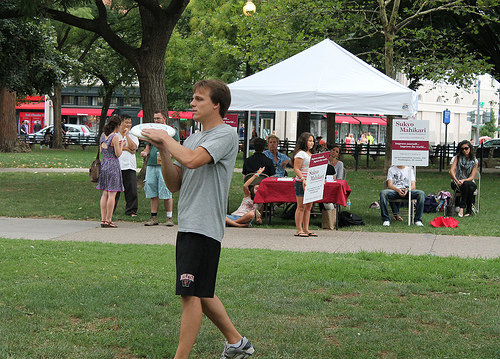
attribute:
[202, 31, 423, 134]
tent — red, white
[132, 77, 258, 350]
man — present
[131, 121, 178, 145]
frisbee — present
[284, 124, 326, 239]
girl — standing, sitting, waving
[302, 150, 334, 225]
sign — blue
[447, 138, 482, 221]
woman — sitting, dressed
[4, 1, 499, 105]
trees — oak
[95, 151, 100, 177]
purse — brown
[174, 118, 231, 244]
shirt — gray, white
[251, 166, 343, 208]
table cloth — red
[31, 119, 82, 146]
car — grey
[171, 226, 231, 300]
shorts — black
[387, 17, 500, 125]
sky — golden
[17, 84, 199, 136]
shops — present